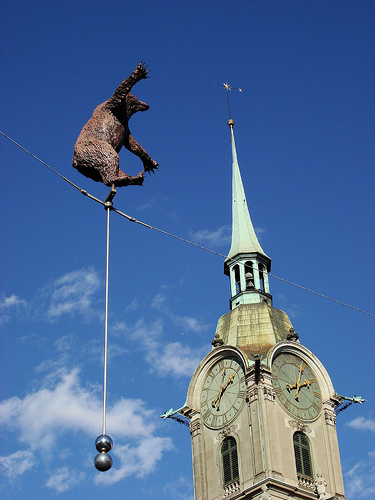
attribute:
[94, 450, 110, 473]
ball — silver, metal 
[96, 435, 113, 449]
ball — silver, metal 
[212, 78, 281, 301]
top — pointed 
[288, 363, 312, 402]
hands — golden , colored 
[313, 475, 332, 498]
statue — small , stone 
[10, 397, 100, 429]
clouds — white 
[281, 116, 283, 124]
sky — blue 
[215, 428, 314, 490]
windows — arched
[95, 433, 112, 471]
balls — silver, shiny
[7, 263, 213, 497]
clouds — white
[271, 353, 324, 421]
clock — round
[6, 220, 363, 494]
clouds — wispy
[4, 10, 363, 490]
sky — clear, blue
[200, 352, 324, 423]
clocks — blue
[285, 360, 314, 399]
hands — gold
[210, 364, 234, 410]
hands — gold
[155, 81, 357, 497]
tower — grey, blue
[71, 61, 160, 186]
bear statue — brown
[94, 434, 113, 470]
balls — large, metal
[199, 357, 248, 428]
clock — round